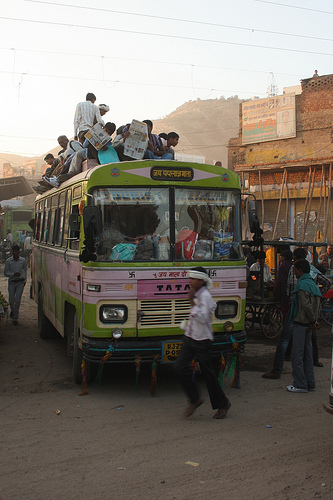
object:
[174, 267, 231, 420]
man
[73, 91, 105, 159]
man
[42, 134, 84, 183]
man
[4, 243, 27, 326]
man